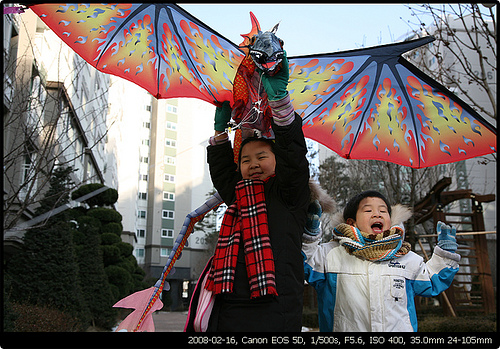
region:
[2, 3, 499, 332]
the large colorful kite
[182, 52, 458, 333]
the two children standing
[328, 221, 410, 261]
the scarf on the child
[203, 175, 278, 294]
the scarf on the child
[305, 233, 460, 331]
the jacket on the child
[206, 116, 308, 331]
the jacket on the child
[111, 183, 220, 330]
the tail of the kite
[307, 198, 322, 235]
the glove on the child's hand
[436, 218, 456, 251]
the glove on the child's hand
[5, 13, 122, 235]
the bare tree branches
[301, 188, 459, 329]
the child wearing blue gloves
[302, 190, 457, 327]
the child in a blue and white coat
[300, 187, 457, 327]
the child with an open mouth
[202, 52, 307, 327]
the child holding a large kite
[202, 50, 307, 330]
the child wearing a red plaid scarf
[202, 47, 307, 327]
the child wearing a black coat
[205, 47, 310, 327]
the child wearing green gloves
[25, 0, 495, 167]
a large kite with wings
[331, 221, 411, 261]
the scarf wrapped around the shorter child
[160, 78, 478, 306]
2 kids posing for a picture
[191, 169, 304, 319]
the scarf is plaid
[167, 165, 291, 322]
the scarf is red, black, and white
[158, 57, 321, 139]
the girl is wearing gloves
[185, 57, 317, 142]
the gloves are green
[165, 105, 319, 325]
the girl is wearing a black coat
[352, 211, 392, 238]
the mouth is open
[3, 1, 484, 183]
the kite is a dragon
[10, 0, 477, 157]
the wings are open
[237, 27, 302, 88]
the head is grey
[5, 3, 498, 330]
a scene outside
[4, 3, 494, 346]
a image of downtown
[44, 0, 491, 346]
two kids playing with a kite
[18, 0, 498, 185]
a kite that looks like a dragon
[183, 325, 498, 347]
a watermark on the right lower corner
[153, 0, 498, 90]
a blue sky with no clouds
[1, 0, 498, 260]
a few buildings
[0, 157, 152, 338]
some trees on the left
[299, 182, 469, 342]
a happy Asian kid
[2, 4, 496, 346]
scene during the day time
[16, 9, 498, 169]
The kite is a dragon.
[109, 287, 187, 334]
The end of the tail is pink.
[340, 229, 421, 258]
Scarf around the boy's neck.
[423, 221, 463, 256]
The glove is blue.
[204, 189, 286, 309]
Scarf around the girl's neck.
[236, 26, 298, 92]
The girl is holding the dragon kite up.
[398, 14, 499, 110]
There are no leaves on the tree.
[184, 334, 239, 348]
The date typed on the bottom.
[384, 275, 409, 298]
Writing on the pocket.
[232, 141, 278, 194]
The girl is smiling.